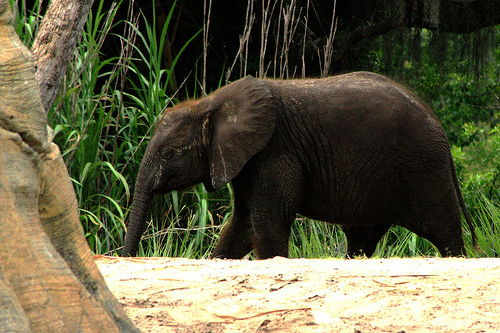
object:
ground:
[82, 257, 499, 333]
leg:
[249, 176, 298, 257]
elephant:
[123, 71, 479, 259]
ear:
[207, 74, 278, 191]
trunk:
[119, 153, 152, 259]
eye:
[163, 149, 175, 159]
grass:
[7, 3, 498, 259]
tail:
[447, 136, 480, 254]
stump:
[0, 19, 141, 331]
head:
[117, 73, 281, 257]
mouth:
[156, 178, 173, 195]